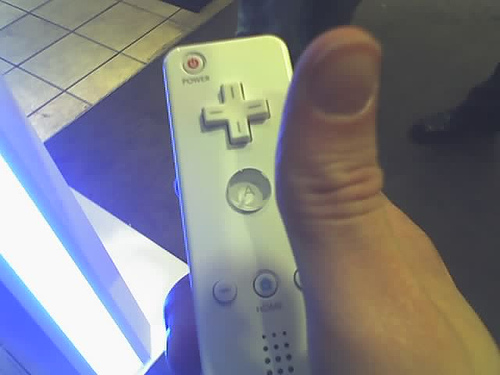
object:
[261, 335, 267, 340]
dot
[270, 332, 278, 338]
dot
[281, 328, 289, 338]
dot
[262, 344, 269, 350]
dot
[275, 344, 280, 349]
dot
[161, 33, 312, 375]
controller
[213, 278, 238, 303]
button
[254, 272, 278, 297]
button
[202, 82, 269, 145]
button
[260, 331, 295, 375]
speaker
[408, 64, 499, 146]
black shoe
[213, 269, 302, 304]
button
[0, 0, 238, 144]
floor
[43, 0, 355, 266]
carpet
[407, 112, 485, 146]
foot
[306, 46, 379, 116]
nail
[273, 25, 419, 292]
finger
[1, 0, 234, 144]
tile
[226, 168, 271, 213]
button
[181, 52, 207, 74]
button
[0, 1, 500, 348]
ground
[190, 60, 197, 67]
symbol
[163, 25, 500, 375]
hand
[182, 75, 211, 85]
word